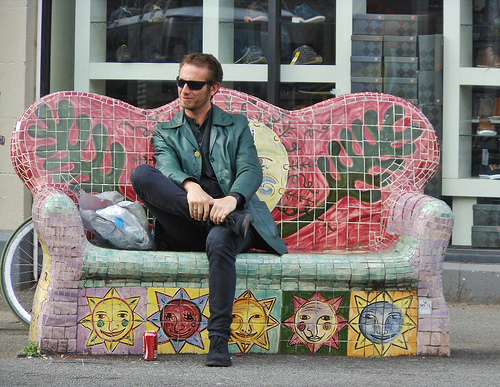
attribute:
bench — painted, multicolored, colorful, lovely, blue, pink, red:
[11, 88, 452, 362]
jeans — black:
[132, 163, 255, 344]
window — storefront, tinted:
[105, 2, 337, 109]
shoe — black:
[208, 337, 232, 366]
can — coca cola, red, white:
[142, 331, 159, 362]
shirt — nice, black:
[185, 104, 229, 200]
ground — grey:
[2, 289, 498, 385]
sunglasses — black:
[175, 77, 210, 89]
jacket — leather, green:
[151, 104, 289, 254]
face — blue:
[360, 300, 407, 344]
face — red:
[160, 300, 201, 339]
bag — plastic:
[73, 188, 158, 251]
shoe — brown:
[113, 43, 131, 62]